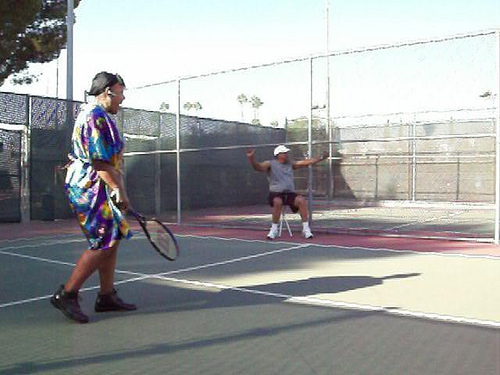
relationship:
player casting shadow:
[48, 69, 184, 327] [105, 270, 423, 318]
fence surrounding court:
[1, 88, 499, 224] [1, 202, 499, 374]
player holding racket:
[48, 69, 184, 327] [105, 189, 183, 265]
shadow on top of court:
[105, 270, 423, 318] [1, 202, 499, 374]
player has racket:
[48, 69, 184, 327] [105, 189, 183, 265]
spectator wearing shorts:
[242, 139, 333, 242] [268, 189, 302, 214]